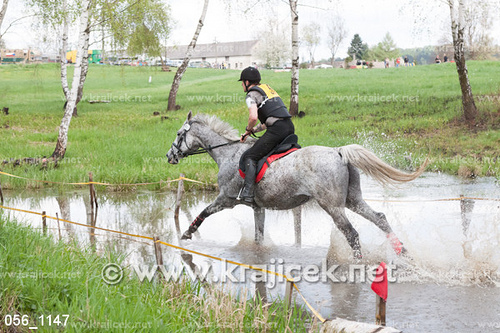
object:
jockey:
[165, 66, 298, 203]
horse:
[164, 110, 430, 259]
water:
[11, 176, 499, 331]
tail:
[337, 143, 426, 189]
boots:
[240, 156, 258, 202]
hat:
[238, 67, 262, 83]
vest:
[247, 81, 291, 120]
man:
[232, 66, 296, 204]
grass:
[106, 123, 145, 169]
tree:
[50, 4, 93, 160]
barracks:
[5, 57, 496, 329]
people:
[393, 56, 402, 66]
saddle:
[239, 134, 300, 185]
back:
[235, 127, 337, 163]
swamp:
[4, 173, 497, 330]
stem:
[59, 27, 77, 115]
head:
[163, 113, 210, 165]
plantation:
[11, 67, 496, 329]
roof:
[108, 41, 257, 55]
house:
[100, 39, 269, 72]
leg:
[312, 195, 361, 261]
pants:
[242, 119, 296, 190]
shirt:
[244, 83, 290, 116]